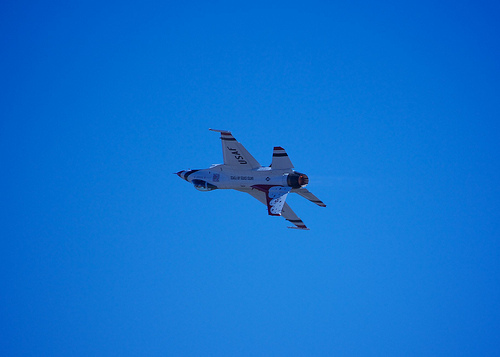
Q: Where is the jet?
A: Sky.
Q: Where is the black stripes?
A: Tip of the wings.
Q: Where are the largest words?
A: Bottom of the wing.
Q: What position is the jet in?
A: Upside down.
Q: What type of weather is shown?
A: Clear.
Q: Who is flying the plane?
A: Pilot.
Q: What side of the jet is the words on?
A: Top.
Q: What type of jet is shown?
A: Air Force.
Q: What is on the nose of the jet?
A: Stripes.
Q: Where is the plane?
A: In the sky.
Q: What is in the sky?
A: A plane.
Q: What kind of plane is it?
A: A jet.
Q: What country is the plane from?
A: USA.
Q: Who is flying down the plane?
A: A pilot.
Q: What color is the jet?
A: Gray.